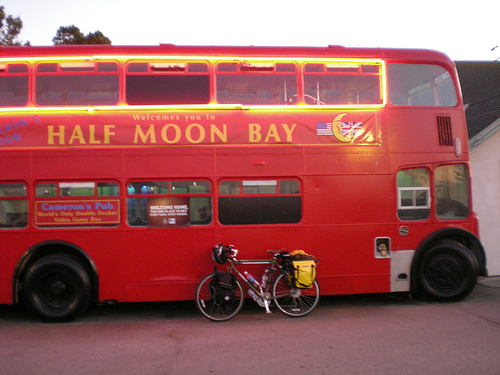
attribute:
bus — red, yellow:
[1, 32, 466, 314]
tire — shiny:
[25, 260, 92, 314]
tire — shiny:
[415, 236, 475, 306]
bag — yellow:
[280, 247, 320, 289]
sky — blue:
[370, 7, 454, 40]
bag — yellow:
[287, 244, 322, 293]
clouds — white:
[15, 4, 88, 26]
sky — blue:
[6, 2, 498, 57]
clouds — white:
[270, 9, 302, 36]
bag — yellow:
[288, 246, 318, 289]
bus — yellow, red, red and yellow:
[2, 45, 484, 321]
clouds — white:
[96, 0, 233, 31]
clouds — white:
[0, 0, 498, 62]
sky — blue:
[0, 0, 500, 62]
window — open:
[215, 175, 304, 225]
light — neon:
[0, 55, 389, 114]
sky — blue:
[203, 1, 477, 41]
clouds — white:
[153, 3, 199, 29]